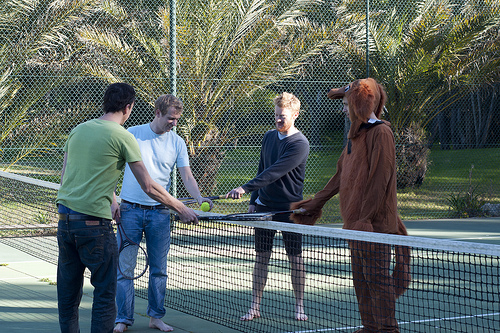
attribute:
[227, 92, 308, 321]
man — red headed, meeting up, bare foot, pointing, shoeless, barefoot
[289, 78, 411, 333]
man — dressed up, wearing costume, costumed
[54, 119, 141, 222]
shirt — green, wrinkled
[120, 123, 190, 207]
shirt — blue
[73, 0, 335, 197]
bush — short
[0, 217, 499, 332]
court — green, white lined, here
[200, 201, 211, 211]
ball — small, for tennis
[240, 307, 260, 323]
foot — shoeless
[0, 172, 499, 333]
net — white, black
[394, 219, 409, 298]
tail — brown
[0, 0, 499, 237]
fence — here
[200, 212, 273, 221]
racket — blue